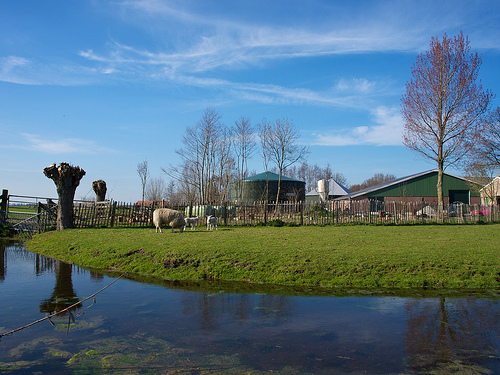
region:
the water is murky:
[55, 258, 135, 330]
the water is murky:
[191, 295, 268, 358]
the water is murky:
[254, 325, 413, 367]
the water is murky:
[79, 260, 176, 339]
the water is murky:
[231, 304, 348, 374]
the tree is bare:
[163, 115, 223, 205]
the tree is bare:
[226, 109, 282, 190]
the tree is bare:
[383, 50, 479, 200]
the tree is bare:
[202, 95, 312, 217]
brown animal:
[148, 200, 182, 237]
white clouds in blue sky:
[22, 23, 76, 68]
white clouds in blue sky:
[80, 17, 135, 72]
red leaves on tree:
[394, 37, 479, 213]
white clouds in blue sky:
[130, 25, 175, 82]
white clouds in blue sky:
[217, 26, 249, 59]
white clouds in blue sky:
[275, 18, 309, 67]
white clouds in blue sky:
[290, 80, 321, 105]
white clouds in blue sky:
[347, 88, 379, 135]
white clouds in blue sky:
[338, 11, 402, 45]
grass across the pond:
[26, 218, 498, 295]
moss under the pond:
[1, 309, 498, 373]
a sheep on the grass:
[144, 203, 191, 236]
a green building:
[342, 165, 489, 211]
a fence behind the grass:
[39, 192, 496, 224]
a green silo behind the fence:
[237, 161, 305, 201]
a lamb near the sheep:
[203, 213, 218, 228]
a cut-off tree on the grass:
[35, 160, 84, 230]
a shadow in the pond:
[30, 252, 89, 324]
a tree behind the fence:
[391, 25, 495, 215]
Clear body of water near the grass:
[3, 241, 498, 373]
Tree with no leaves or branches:
[42, 157, 89, 231]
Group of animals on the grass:
[148, 207, 219, 235]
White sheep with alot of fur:
[147, 201, 188, 241]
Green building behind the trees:
[231, 173, 307, 222]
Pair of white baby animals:
[185, 213, 220, 232]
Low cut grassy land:
[29, 223, 499, 292]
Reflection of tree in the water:
[401, 290, 490, 374]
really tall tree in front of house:
[393, 32, 499, 227]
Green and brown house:
[338, 169, 498, 222]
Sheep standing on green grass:
[152, 205, 188, 235]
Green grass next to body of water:
[26, 223, 498, 290]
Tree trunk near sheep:
[40, 157, 87, 228]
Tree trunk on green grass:
[42, 158, 88, 229]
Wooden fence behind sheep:
[38, 198, 498, 228]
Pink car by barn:
[470, 203, 495, 218]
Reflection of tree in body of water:
[395, 293, 498, 370]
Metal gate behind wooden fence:
[6, 194, 100, 229]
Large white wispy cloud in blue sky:
[81, 21, 432, 78]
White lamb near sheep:
[202, 210, 219, 231]